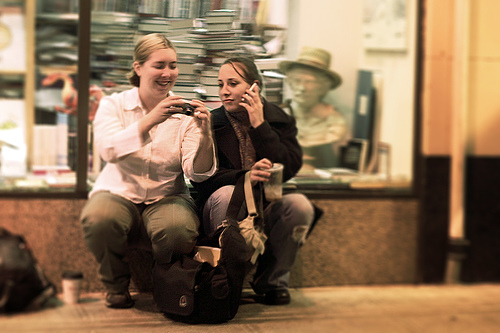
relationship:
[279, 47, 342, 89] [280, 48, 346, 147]
hat on bust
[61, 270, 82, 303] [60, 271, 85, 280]
coffe cup has lid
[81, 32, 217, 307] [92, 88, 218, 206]
woman wearing a shirt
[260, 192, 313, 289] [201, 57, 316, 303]
leg of woman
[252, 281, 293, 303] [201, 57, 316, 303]
shoe on woman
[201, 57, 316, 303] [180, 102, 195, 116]
woman looking at camera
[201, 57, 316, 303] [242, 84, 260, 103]
woman holding cellphone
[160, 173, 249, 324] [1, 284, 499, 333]
bag on sidewalk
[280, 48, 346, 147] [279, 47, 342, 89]
bust wearing a hat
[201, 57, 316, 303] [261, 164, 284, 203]
woman holding cup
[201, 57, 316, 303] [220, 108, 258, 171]
woman wearing a scarf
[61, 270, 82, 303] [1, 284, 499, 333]
coffe cup on sidewalk